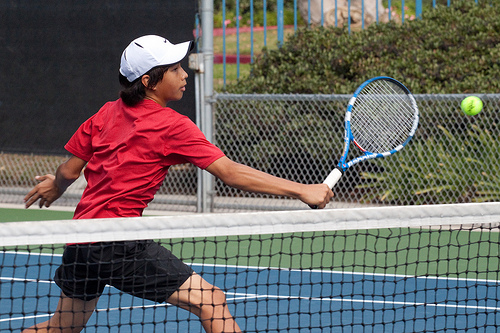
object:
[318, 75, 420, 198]
racket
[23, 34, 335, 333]
boy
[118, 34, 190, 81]
cap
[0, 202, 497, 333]
net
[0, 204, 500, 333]
tennis court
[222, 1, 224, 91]
post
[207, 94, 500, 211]
fence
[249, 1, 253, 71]
post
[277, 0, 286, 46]
post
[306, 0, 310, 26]
post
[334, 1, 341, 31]
post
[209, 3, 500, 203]
bush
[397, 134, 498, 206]
bush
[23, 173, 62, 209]
hand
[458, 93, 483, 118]
tennis ball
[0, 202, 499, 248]
edge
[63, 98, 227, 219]
shirt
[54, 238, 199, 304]
shorts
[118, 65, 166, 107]
hair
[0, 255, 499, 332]
part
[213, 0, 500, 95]
fence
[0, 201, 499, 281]
area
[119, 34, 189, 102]
head